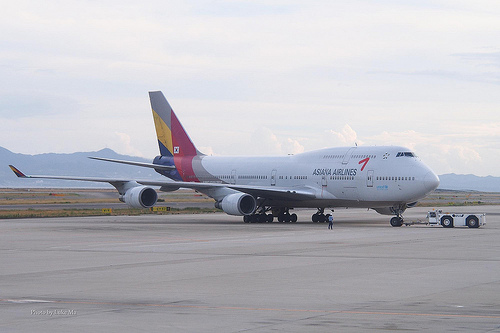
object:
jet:
[27, 150, 434, 209]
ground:
[270, 229, 357, 247]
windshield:
[394, 148, 415, 161]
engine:
[116, 185, 159, 209]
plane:
[9, 85, 492, 285]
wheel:
[389, 215, 405, 227]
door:
[362, 164, 377, 189]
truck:
[425, 208, 488, 228]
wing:
[6, 154, 323, 216]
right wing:
[5, 161, 316, 216]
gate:
[373, 204, 490, 229]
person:
[325, 213, 335, 230]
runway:
[0, 229, 500, 320]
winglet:
[6, 162, 33, 178]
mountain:
[0, 142, 115, 173]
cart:
[426, 208, 487, 228]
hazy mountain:
[438, 172, 498, 193]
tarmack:
[17, 210, 498, 328]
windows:
[385, 171, 405, 191]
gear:
[310, 209, 336, 224]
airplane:
[7, 88, 442, 227]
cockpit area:
[389, 151, 418, 160]